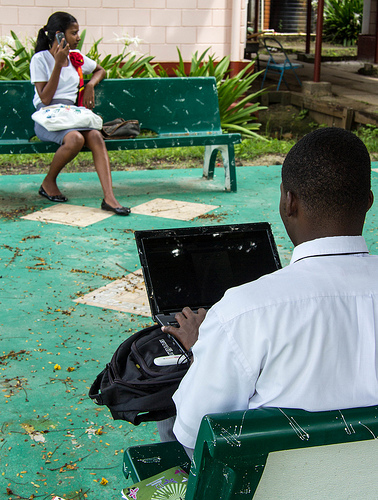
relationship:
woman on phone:
[30, 11, 132, 217] [56, 31, 69, 51]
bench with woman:
[0, 78, 242, 192] [30, 11, 132, 217]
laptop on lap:
[134, 221, 283, 362] [156, 359, 189, 440]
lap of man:
[156, 359, 189, 440] [160, 127, 376, 451]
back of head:
[308, 143, 367, 200] [279, 130, 373, 247]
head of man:
[279, 130, 373, 247] [160, 127, 376, 451]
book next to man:
[122, 459, 192, 499] [160, 127, 376, 451]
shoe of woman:
[39, 186, 69, 202] [30, 11, 132, 217]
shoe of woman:
[101, 199, 132, 215] [30, 11, 132, 217]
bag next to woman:
[101, 117, 141, 139] [30, 11, 132, 217]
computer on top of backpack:
[134, 221, 283, 362] [88, 324, 194, 427]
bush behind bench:
[3, 31, 38, 81] [0, 78, 242, 192]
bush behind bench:
[77, 29, 158, 78] [0, 78, 242, 192]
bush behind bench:
[145, 51, 273, 142] [0, 78, 242, 192]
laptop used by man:
[134, 221, 283, 362] [160, 127, 376, 451]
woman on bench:
[30, 11, 132, 217] [0, 78, 242, 192]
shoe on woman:
[39, 186, 69, 202] [30, 11, 132, 217]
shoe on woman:
[101, 199, 132, 215] [30, 11, 132, 217]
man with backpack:
[160, 127, 376, 451] [88, 324, 194, 427]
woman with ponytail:
[30, 11, 132, 217] [35, 24, 51, 54]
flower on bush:
[112, 32, 147, 48] [77, 29, 158, 78]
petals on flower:
[109, 33, 147, 49] [112, 32, 147, 48]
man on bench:
[160, 127, 376, 451] [122, 405, 377, 499]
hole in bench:
[28, 135, 42, 144] [0, 78, 242, 192]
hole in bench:
[135, 128, 160, 138] [0, 78, 242, 192]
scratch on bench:
[137, 455, 161, 464] [122, 405, 377, 499]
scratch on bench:
[221, 410, 248, 451] [122, 405, 377, 499]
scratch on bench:
[278, 407, 311, 440] [122, 405, 377, 499]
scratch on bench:
[338, 409, 356, 436] [122, 405, 377, 499]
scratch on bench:
[234, 482, 253, 496] [122, 405, 377, 499]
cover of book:
[123, 464, 193, 499] [122, 459, 192, 499]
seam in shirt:
[222, 281, 376, 326] [172, 235, 377, 447]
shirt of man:
[172, 235, 377, 447] [160, 127, 376, 451]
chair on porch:
[261, 36, 305, 92] [247, 56, 378, 116]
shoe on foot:
[39, 186, 69, 202] [42, 185, 67, 203]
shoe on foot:
[101, 199, 132, 215] [103, 201, 124, 210]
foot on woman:
[42, 185, 67, 203] [30, 11, 132, 217]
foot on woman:
[103, 201, 124, 210] [30, 11, 132, 217]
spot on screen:
[171, 248, 181, 257] [142, 230, 279, 314]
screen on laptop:
[142, 230, 279, 314] [134, 221, 283, 362]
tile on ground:
[124, 198, 221, 223] [0, 133, 376, 499]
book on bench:
[122, 459, 192, 499] [122, 405, 377, 499]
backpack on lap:
[88, 324, 194, 427] [156, 359, 189, 440]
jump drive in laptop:
[153, 354, 193, 368] [134, 221, 283, 362]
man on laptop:
[160, 127, 376, 451] [134, 221, 283, 362]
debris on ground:
[0, 202, 229, 499] [0, 133, 376, 499]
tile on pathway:
[124, 198, 221, 223] [0, 161, 377, 500]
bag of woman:
[101, 117, 141, 139] [30, 11, 132, 217]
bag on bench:
[101, 117, 141, 139] [0, 78, 242, 192]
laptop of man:
[134, 221, 283, 362] [160, 127, 376, 451]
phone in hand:
[56, 31, 69, 51] [54, 38, 70, 64]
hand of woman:
[54, 38, 70, 64] [30, 11, 132, 217]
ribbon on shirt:
[70, 50, 86, 108] [30, 50, 99, 104]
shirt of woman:
[30, 50, 99, 104] [30, 11, 132, 217]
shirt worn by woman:
[30, 50, 99, 104] [30, 11, 132, 217]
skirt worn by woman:
[34, 99, 101, 144] [30, 11, 132, 217]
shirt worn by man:
[172, 235, 377, 447] [160, 127, 376, 451]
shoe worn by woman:
[39, 186, 69, 202] [30, 11, 132, 217]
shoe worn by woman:
[101, 199, 132, 215] [30, 11, 132, 217]